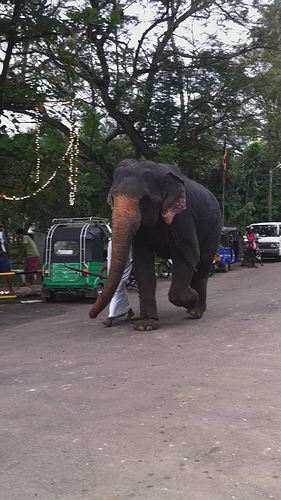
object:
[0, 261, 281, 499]
road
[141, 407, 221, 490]
spots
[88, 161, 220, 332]
elephant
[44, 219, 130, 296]
cars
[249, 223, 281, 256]
cars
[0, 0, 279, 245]
trees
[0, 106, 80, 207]
lights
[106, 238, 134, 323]
clothes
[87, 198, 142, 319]
trunk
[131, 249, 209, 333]
legs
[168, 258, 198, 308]
high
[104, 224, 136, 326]
person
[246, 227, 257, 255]
person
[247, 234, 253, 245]
red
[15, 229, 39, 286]
person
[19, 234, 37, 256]
green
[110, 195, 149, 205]
eyes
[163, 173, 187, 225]
ear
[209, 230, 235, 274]
vehicle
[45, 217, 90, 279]
railing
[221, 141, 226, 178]
flag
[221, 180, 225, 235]
pole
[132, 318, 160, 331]
foot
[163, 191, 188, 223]
pink